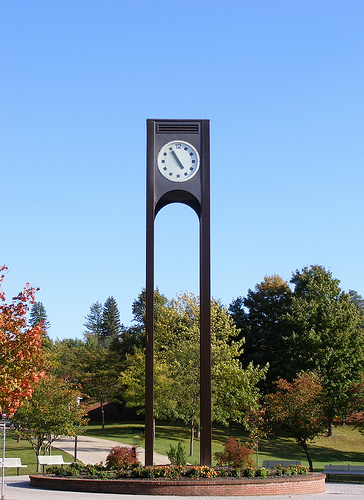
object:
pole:
[200, 120, 211, 465]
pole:
[145, 118, 154, 464]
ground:
[79, 438, 103, 459]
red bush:
[213, 437, 257, 466]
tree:
[265, 369, 333, 473]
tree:
[117, 290, 271, 457]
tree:
[67, 347, 129, 435]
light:
[74, 396, 84, 463]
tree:
[265, 262, 364, 436]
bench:
[262, 459, 301, 469]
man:
[0, 1, 362, 114]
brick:
[256, 484, 261, 487]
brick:
[283, 483, 288, 486]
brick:
[181, 485, 188, 488]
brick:
[312, 480, 318, 483]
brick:
[230, 486, 236, 489]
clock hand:
[171, 150, 185, 169]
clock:
[145, 117, 210, 466]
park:
[0, 3, 362, 497]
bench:
[36, 454, 73, 475]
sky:
[113, 119, 141, 146]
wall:
[141, 483, 286, 496]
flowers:
[146, 464, 185, 478]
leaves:
[30, 329, 40, 339]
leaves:
[1, 309, 14, 326]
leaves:
[298, 378, 308, 386]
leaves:
[224, 449, 233, 457]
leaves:
[124, 452, 134, 458]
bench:
[0, 457, 28, 479]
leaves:
[18, 290, 33, 306]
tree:
[0, 260, 50, 421]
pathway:
[42, 431, 194, 466]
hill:
[1, 377, 362, 471]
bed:
[28, 464, 328, 497]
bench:
[321, 463, 364, 483]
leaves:
[0, 354, 19, 405]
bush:
[104, 445, 142, 472]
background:
[19, 380, 361, 473]